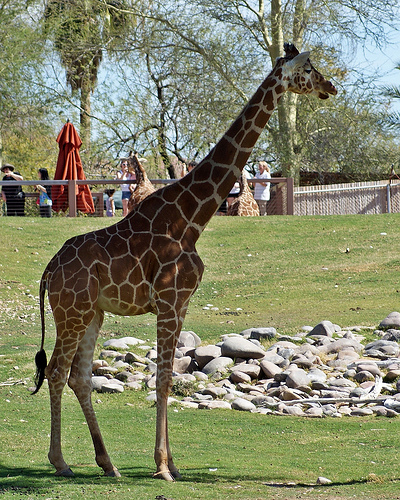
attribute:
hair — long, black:
[37, 160, 61, 182]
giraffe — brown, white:
[43, 47, 345, 361]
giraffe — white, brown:
[35, 145, 212, 422]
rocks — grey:
[99, 313, 398, 441]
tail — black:
[29, 273, 46, 396]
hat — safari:
[0, 162, 16, 174]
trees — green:
[44, 2, 137, 151]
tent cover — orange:
[53, 118, 95, 212]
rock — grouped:
[219, 335, 264, 359]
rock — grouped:
[260, 358, 282, 378]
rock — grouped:
[285, 369, 310, 389]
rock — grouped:
[232, 397, 255, 410]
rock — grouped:
[203, 386, 228, 396]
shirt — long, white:
[252, 171, 270, 200]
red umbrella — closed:
[34, 91, 119, 210]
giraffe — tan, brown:
[40, 47, 338, 488]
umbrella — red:
[50, 119, 95, 215]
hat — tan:
[0, 156, 16, 174]